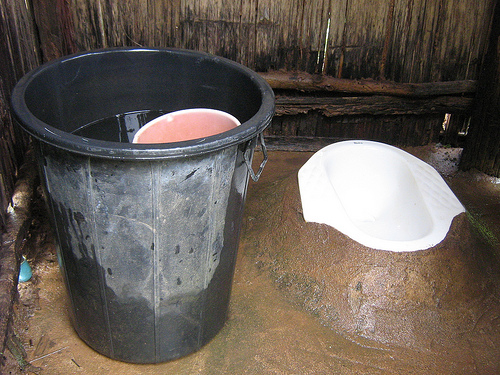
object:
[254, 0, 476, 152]
wood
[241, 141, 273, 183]
handle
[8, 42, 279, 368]
garbage can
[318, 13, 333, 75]
crack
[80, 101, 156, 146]
water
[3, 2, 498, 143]
rotten wood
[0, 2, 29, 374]
rotten wood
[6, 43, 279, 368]
bucket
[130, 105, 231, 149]
object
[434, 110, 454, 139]
hole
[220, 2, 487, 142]
wall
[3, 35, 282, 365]
garbage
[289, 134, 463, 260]
hole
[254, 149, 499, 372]
ground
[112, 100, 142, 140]
reflection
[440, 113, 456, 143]
crack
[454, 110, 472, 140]
crack